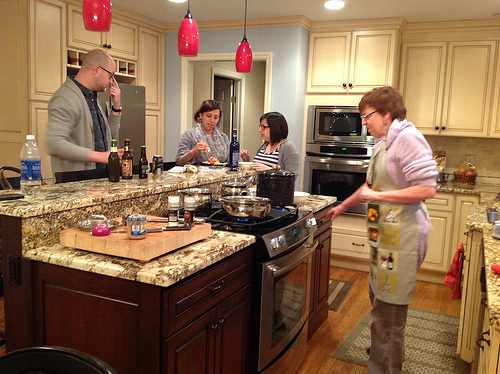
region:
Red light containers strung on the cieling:
[76, 1, 290, 75]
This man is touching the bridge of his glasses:
[44, 45, 146, 177]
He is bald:
[64, 38, 134, 103]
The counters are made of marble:
[6, 137, 360, 289]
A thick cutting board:
[50, 190, 235, 271]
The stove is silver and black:
[188, 150, 339, 371]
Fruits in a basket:
[440, 137, 494, 201]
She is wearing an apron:
[346, 130, 453, 371]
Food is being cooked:
[186, 171, 316, 239]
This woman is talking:
[233, 91, 320, 178]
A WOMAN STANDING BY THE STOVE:
[222, 86, 445, 368]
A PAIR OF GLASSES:
[96, 62, 121, 82]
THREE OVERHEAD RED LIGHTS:
[81, 1, 299, 81]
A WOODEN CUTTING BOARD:
[56, 203, 218, 264]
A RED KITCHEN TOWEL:
[437, 241, 473, 306]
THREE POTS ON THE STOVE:
[208, 156, 293, 226]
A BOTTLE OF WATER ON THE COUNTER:
[12, 127, 60, 222]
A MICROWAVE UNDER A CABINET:
[306, 103, 376, 150]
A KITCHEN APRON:
[352, 141, 428, 311]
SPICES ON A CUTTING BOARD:
[121, 191, 201, 238]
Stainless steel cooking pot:
[220, 191, 270, 217]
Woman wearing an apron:
[357, 80, 430, 371]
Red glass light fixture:
[177, 10, 197, 56]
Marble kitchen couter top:
[48, 180, 113, 210]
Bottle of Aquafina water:
[18, 132, 39, 197]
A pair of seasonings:
[167, 192, 193, 224]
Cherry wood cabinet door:
[315, 228, 330, 313]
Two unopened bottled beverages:
[107, 135, 133, 181]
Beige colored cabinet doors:
[425, 36, 497, 131]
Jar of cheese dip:
[126, 213, 146, 239]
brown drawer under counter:
[167, 279, 279, 316]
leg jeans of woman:
[363, 283, 420, 363]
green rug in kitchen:
[412, 290, 457, 368]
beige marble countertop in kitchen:
[31, 160, 146, 231]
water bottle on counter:
[11, 105, 83, 208]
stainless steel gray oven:
[245, 225, 363, 350]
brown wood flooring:
[310, 297, 366, 364]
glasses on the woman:
[347, 104, 387, 129]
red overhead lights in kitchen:
[165, 27, 239, 94]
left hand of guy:
[95, 75, 130, 104]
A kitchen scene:
[17, 23, 472, 343]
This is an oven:
[254, 249, 330, 366]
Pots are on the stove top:
[186, 164, 303, 231]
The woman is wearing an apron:
[331, 77, 436, 338]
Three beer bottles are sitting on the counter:
[101, 131, 154, 186]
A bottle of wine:
[223, 125, 246, 175]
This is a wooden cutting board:
[59, 209, 213, 259]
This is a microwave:
[311, 104, 363, 142]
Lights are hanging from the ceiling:
[78, 2, 283, 74]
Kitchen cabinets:
[305, 29, 402, 92]